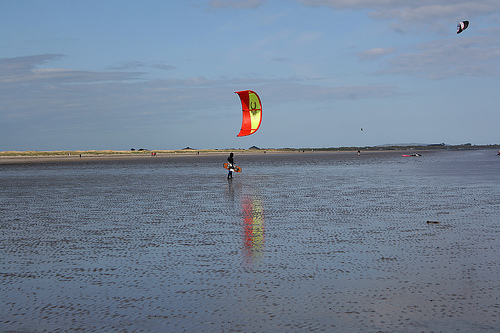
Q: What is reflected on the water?
A: A kite.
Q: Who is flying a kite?
A: A man.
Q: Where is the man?
A: In the water.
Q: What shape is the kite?
A: Curved.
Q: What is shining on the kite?
A: The sun.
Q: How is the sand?
A: Wet.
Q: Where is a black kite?
A: In the air.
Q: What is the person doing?
A: Parasailing.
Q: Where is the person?
A: On the beach.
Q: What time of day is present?
A: Low tide.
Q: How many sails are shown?
A: One.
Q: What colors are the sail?
A: Red and Yellow.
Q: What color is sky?
A: Blue.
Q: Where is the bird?
A: In sky.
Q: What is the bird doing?
A: Flying.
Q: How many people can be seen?
A: One.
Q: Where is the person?
A: In water.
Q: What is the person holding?
A: Surfboard.